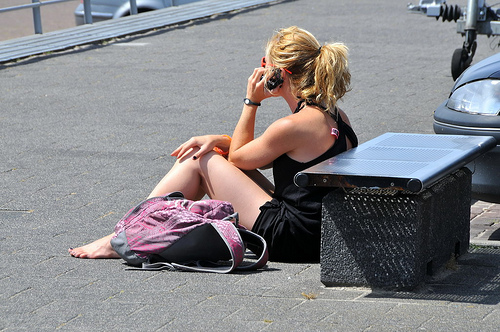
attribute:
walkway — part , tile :
[1, 2, 498, 330]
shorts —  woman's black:
[252, 194, 313, 265]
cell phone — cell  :
[261, 66, 285, 89]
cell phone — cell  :
[262, 70, 287, 93]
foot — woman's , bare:
[60, 219, 120, 274]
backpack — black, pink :
[101, 167, 268, 273]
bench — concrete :
[10, 19, 71, 41]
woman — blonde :
[78, 27, 349, 257]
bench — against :
[299, 129, 494, 279]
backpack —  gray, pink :
[111, 183, 276, 270]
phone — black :
[260, 64, 292, 92]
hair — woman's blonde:
[264, 12, 362, 118]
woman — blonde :
[103, 22, 413, 309]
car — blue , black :
[431, 54, 498, 202]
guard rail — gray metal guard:
[8, 2, 155, 50]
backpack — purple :
[108, 190, 275, 278]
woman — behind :
[68, 20, 363, 300]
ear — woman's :
[267, 64, 289, 86]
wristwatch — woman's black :
[238, 92, 267, 113]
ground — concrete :
[5, 4, 484, 316]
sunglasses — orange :
[257, 52, 296, 81]